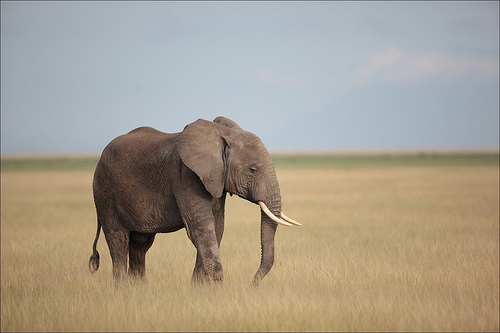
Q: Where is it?
A: This is at the plain.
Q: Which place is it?
A: It is a plain.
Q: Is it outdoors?
A: Yes, it is outdoors.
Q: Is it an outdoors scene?
A: Yes, it is outdoors.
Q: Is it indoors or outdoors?
A: It is outdoors.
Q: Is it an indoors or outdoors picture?
A: It is outdoors.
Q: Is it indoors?
A: No, it is outdoors.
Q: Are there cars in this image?
A: No, there are no cars.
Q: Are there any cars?
A: No, there are no cars.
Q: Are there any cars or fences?
A: No, there are no cars or fences.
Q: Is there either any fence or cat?
A: No, there are no fences or cats.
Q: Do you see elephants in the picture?
A: Yes, there is an elephant.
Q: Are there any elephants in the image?
A: Yes, there is an elephant.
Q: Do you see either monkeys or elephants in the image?
A: Yes, there is an elephant.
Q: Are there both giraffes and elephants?
A: No, there is an elephant but no giraffes.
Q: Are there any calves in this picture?
A: No, there are no calves.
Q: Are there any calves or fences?
A: No, there are no calves or fences.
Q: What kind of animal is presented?
A: The animal is an elephant.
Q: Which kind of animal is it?
A: The animal is an elephant.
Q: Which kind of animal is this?
A: This is an elephant.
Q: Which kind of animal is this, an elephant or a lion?
A: This is an elephant.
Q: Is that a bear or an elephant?
A: That is an elephant.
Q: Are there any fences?
A: No, there are no fences.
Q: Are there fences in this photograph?
A: No, there are no fences.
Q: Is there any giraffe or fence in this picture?
A: No, there are no fences or giraffes.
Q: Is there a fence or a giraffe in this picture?
A: No, there are no fences or giraffes.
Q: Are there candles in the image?
A: No, there are no candles.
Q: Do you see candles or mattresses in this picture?
A: No, there are no candles or mattresses.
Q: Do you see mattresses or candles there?
A: No, there are no candles or mattresses.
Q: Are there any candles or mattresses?
A: No, there are no candles or mattresses.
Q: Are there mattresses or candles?
A: No, there are no candles or mattresses.